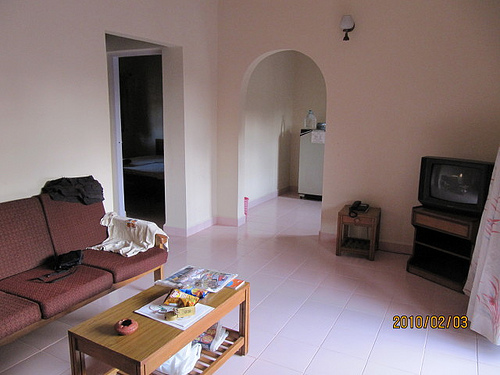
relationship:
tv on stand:
[422, 157, 498, 215] [408, 206, 471, 295]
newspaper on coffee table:
[154, 266, 231, 307] [64, 324, 167, 370]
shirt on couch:
[95, 209, 169, 269] [10, 202, 102, 239]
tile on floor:
[306, 288, 353, 326] [237, 241, 303, 261]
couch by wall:
[10, 202, 102, 239] [37, 94, 97, 121]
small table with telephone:
[331, 211, 379, 260] [342, 187, 368, 215]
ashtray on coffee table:
[106, 320, 148, 333] [64, 324, 167, 370]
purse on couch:
[26, 259, 98, 294] [10, 202, 102, 239]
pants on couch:
[35, 174, 100, 209] [10, 202, 102, 239]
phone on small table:
[349, 198, 389, 222] [331, 211, 379, 260]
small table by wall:
[331, 211, 379, 260] [37, 94, 97, 121]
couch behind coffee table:
[10, 202, 102, 239] [64, 324, 167, 370]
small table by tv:
[331, 211, 379, 260] [422, 157, 498, 215]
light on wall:
[326, 12, 375, 48] [37, 94, 97, 121]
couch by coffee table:
[10, 202, 102, 239] [64, 324, 167, 370]